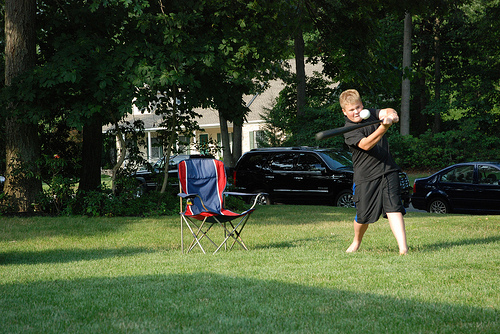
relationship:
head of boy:
[339, 86, 363, 123] [336, 87, 409, 256]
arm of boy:
[345, 110, 397, 151] [336, 87, 409, 256]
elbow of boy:
[358, 142, 370, 151] [336, 87, 409, 256]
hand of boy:
[380, 104, 396, 125] [336, 87, 409, 256]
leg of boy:
[380, 174, 408, 256] [336, 87, 409, 256]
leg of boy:
[345, 178, 382, 254] [336, 87, 409, 256]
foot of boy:
[345, 248, 355, 252] [336, 87, 409, 256]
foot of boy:
[401, 252, 408, 258] [336, 87, 409, 256]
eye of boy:
[354, 104, 361, 109] [336, 87, 409, 256]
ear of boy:
[339, 106, 348, 119] [336, 87, 409, 256]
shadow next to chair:
[0, 272, 498, 332] [176, 157, 269, 252]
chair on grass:
[176, 157, 269, 252] [2, 204, 499, 333]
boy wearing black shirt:
[336, 87, 409, 256] [343, 114, 399, 186]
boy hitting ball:
[336, 87, 409, 256] [359, 107, 370, 122]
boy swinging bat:
[339, 87, 409, 257] [314, 116, 384, 150]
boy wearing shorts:
[339, 87, 409, 257] [353, 172, 405, 225]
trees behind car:
[217, 1, 498, 187] [411, 163, 499, 214]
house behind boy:
[102, 56, 340, 174] [339, 87, 409, 257]